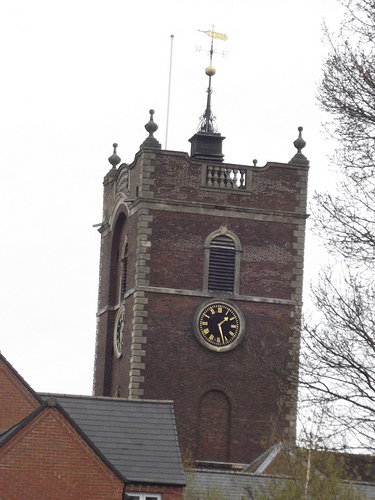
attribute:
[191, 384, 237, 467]
arch — brick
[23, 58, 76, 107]
sky — blue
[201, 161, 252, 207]
railing — gray, balcony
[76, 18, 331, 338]
tower — brown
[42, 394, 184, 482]
roof — brown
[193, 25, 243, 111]
vane — weather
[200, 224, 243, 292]
window — arched, louvered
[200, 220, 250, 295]
window — arched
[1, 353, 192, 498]
building — red, brick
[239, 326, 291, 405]
wall — red, brick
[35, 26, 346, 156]
clouds — white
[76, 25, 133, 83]
clouds sky — white, blue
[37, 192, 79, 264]
sky — blue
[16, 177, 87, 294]
clouds — white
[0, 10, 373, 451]
sky — white, blue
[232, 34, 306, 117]
clouds — white 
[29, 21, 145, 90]
sky — white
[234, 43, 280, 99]
clouds — white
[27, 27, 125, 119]
sky — blue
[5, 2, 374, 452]
cloud — white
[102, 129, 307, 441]
clock tower — brown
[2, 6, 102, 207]
clouds — white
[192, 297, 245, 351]
time — 1;26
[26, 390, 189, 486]
roof — gray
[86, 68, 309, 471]
tower — clock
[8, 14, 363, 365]
sky — blue